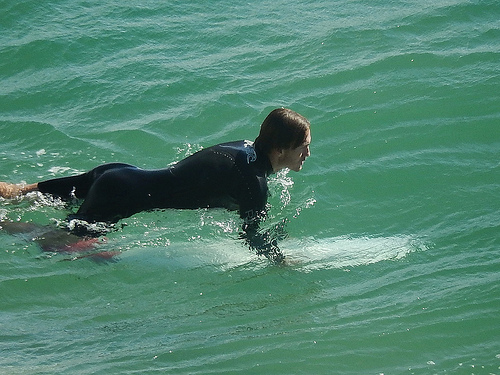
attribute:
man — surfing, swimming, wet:
[0, 106, 312, 263]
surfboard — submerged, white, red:
[117, 234, 412, 273]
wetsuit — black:
[38, 137, 272, 237]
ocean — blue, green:
[2, 0, 498, 374]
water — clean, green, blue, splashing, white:
[3, 3, 500, 373]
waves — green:
[1, 168, 305, 259]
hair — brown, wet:
[257, 108, 311, 160]